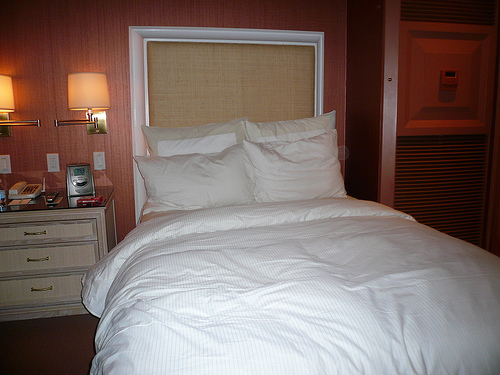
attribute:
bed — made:
[82, 21, 497, 373]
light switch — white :
[92, 146, 108, 173]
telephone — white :
[3, 178, 43, 202]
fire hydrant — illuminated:
[62, 57, 114, 127]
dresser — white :
[0, 196, 120, 321]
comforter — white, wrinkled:
[85, 199, 495, 371]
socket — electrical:
[44, 151, 59, 173]